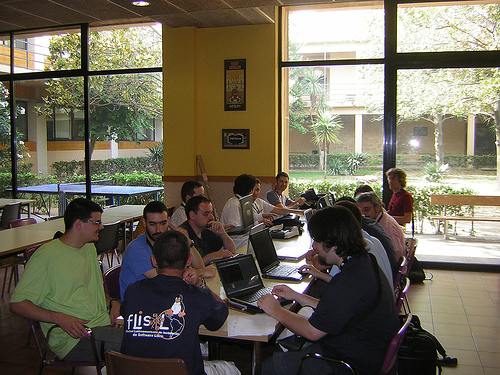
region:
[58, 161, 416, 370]
many guys sitting at a large table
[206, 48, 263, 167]
two pictures on the wall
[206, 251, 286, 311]
man working on a laptop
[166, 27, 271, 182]
wall is yellow with wood detail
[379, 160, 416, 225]
man has curly blonde hair and red shirt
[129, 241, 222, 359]
man wearing black t-shirt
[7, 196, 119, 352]
man with glasses wearing green shirt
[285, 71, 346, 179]
green palm tree outside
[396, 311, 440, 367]
black bag on the ground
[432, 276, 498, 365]
orange square tile on the ground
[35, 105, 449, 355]
There are several people here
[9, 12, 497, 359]
This is a study hall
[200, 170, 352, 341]
Several laptops on the table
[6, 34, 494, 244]
None of the windows have blinds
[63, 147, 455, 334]
Everyone here are men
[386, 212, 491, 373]
The floor is brown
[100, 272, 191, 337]
The shirt says "fLisL"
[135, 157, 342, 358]
The table is made of wood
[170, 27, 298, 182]
This part is yellow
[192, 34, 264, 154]
Two pictures on the wall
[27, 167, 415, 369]
Men sitting at a table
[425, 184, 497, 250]
A wooden bench outside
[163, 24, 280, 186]
A wall painted yellow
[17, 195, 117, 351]
A man in a green tshirt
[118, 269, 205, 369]
A penguin on the back of a tshirt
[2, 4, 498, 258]
Big glass windows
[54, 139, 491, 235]
A courtyard with tables and a bench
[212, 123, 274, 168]
A framed beer sign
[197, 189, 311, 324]
Laptops on a table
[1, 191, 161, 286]
An empty table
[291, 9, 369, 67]
A window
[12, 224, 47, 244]
A long table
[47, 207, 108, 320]
A man wearing a green shirt and glasses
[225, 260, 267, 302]
A laptop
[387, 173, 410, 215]
A man with blonde hair wearing a red shirt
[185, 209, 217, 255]
A man with a goatee wearing a black shirt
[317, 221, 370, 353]
A man with black hair wearing a short sleeved shirt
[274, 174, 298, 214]
A man wearing a grey and red shirt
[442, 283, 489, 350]
A yellow tiled floor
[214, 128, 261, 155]
A picture hanging on the wall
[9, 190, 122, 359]
man in green shirt and grey shorts, dark hair and glasses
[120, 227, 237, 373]
man sitting at the head of the table in a black shirt with penguin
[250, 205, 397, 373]
man sitting in first seat to the right with long dark hair, facial hair and dark shirt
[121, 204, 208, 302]
man in 2nd chair from left with blue t shirt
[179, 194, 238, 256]
man in 3rd chair from left dark short hair, dark shirt and hand to mouth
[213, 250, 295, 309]
laptop the first man on the right is using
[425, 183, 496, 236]
bench sitting outside on the snow covered ground just beyond the glass windows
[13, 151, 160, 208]
ping pong table outside the glass windows far left of picture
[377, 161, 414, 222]
man with light hair and red shirt sitting at the far end right side of table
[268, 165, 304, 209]
man sitting on far left side of the table with short dark hair and grey shirt